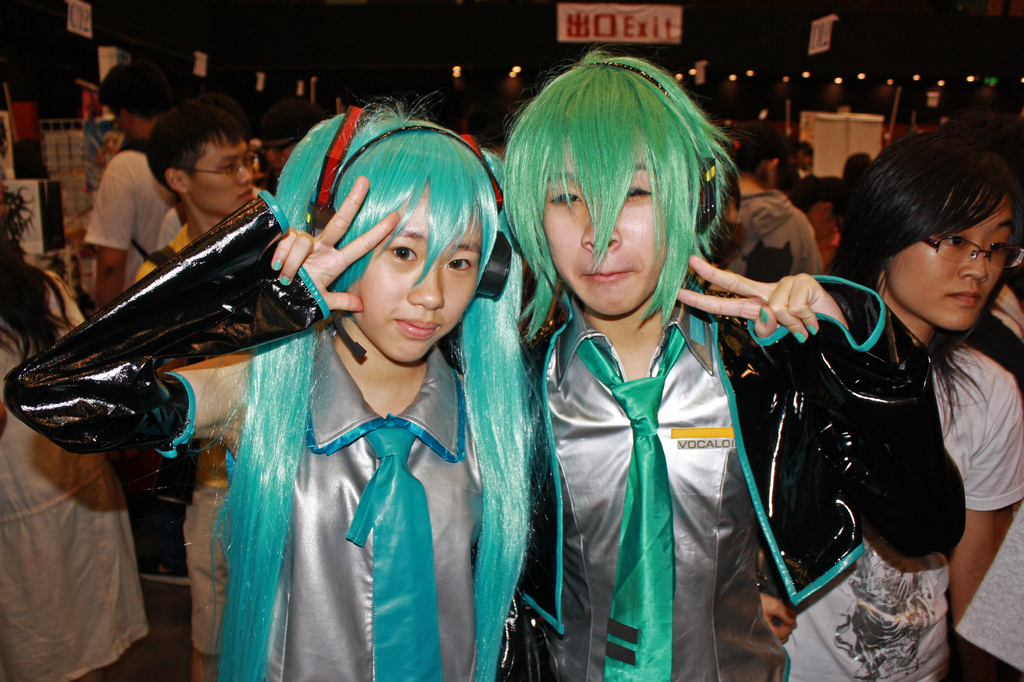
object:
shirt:
[521, 279, 790, 682]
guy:
[503, 50, 961, 681]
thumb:
[323, 292, 364, 312]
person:
[5, 106, 536, 661]